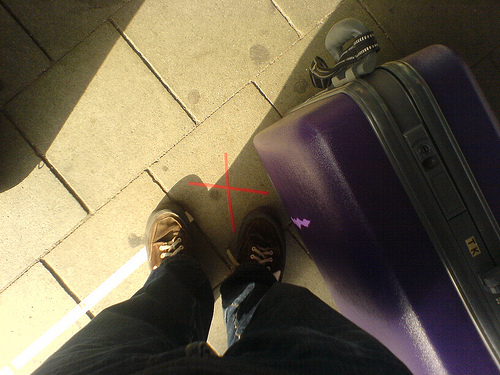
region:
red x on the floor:
[180, 145, 275, 233]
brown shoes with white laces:
[132, 200, 294, 295]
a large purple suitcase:
[240, 24, 489, 371]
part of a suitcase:
[295, 18, 394, 103]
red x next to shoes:
[174, 143, 281, 236]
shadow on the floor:
[10, 13, 125, 189]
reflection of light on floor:
[21, 228, 137, 373]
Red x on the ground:
[170, 160, 280, 235]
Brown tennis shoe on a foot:
[125, 189, 202, 293]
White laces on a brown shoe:
[153, 234, 185, 256]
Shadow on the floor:
[25, 39, 102, 130]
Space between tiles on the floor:
[32, 164, 94, 224]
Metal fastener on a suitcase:
[387, 125, 471, 225]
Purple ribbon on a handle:
[327, 49, 377, 71]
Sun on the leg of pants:
[207, 294, 262, 358]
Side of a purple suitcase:
[303, 184, 355, 255]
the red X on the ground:
[183, 145, 268, 231]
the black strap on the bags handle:
[298, 29, 383, 83]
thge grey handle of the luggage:
[320, 11, 377, 71]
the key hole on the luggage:
[411, 138, 434, 160]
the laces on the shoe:
[249, 240, 274, 272]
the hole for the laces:
[265, 246, 276, 273]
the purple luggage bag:
[247, 20, 498, 362]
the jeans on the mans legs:
[35, 260, 412, 372]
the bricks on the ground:
[0, 183, 106, 311]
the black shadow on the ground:
[0, 0, 149, 202]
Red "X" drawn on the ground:
[192, 152, 267, 230]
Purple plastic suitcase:
[250, 13, 498, 373]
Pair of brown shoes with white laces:
[138, 203, 288, 293]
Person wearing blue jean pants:
[20, 205, 415, 374]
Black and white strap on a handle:
[304, 28, 381, 85]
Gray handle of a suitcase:
[322, 15, 380, 88]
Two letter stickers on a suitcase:
[462, 231, 484, 259]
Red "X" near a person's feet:
[187, 151, 271, 231]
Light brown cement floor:
[1, 1, 498, 373]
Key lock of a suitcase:
[407, 130, 442, 175]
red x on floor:
[184, 150, 276, 232]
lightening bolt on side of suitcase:
[284, 211, 318, 237]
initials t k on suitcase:
[458, 230, 485, 260]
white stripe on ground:
[2, 245, 151, 361]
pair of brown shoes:
[142, 203, 289, 305]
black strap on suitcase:
[306, 28, 383, 84]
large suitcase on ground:
[245, 40, 497, 366]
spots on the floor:
[176, 34, 315, 111]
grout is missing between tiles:
[5, 114, 103, 217]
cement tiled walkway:
[17, 44, 219, 163]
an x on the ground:
[193, 141, 261, 240]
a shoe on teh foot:
[113, 183, 220, 290]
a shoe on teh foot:
[219, 212, 306, 280]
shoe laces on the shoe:
[245, 238, 272, 279]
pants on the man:
[116, 236, 308, 366]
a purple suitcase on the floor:
[270, 114, 475, 283]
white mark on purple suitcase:
[286, 211, 315, 234]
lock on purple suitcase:
[403, 118, 468, 224]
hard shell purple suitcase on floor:
[249, 13, 498, 374]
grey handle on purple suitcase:
[323, 13, 383, 89]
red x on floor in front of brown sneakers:
[178, 146, 274, 241]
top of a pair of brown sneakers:
[141, 199, 292, 287]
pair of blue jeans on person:
[25, 250, 420, 374]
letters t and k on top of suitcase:
[458, 231, 485, 265]